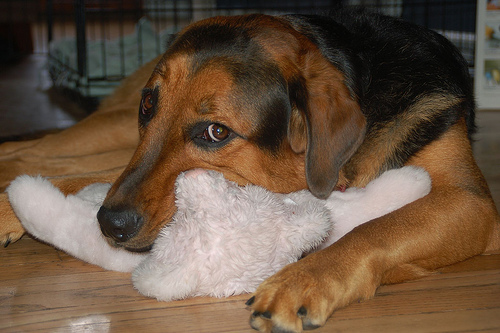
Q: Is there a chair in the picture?
A: No, there are no chairs.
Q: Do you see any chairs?
A: No, there are no chairs.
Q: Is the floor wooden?
A: Yes, the floor is wooden.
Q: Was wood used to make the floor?
A: Yes, the floor is made of wood.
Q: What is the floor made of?
A: The floor is made of wood.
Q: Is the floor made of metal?
A: No, the floor is made of wood.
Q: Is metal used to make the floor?
A: No, the floor is made of wood.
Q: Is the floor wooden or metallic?
A: The floor is wooden.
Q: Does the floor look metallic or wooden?
A: The floor is wooden.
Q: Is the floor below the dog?
A: Yes, the floor is below the dog.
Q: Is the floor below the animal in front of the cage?
A: Yes, the floor is below the dog.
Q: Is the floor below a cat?
A: No, the floor is below the dog.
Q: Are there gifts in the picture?
A: No, there are no gifts.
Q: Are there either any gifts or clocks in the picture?
A: No, there are no gifts or clocks.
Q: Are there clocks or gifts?
A: No, there are no gifts or clocks.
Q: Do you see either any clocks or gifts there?
A: No, there are no gifts or clocks.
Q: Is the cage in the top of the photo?
A: Yes, the cage is in the top of the image.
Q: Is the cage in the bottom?
A: No, the cage is in the top of the image.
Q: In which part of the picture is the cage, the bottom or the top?
A: The cage is in the top of the image.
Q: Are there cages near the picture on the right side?
A: Yes, there is a cage near the picture.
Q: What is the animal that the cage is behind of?
A: The animal is a dog.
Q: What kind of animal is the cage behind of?
A: The cage is behind the dog.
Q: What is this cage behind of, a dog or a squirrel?
A: The cage is behind a dog.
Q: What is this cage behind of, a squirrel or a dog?
A: The cage is behind a dog.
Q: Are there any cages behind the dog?
A: Yes, there is a cage behind the dog.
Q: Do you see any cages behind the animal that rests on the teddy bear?
A: Yes, there is a cage behind the dog.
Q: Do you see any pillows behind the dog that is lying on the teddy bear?
A: No, there is a cage behind the dog.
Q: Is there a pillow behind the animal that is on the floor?
A: No, there is a cage behind the dog.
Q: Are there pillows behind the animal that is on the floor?
A: No, there is a cage behind the dog.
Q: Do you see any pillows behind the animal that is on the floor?
A: No, there is a cage behind the dog.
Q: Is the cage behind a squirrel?
A: No, the cage is behind the dog.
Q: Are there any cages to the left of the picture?
A: Yes, there is a cage to the left of the picture.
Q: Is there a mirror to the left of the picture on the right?
A: No, there is a cage to the left of the picture.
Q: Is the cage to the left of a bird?
A: No, the cage is to the left of the picture.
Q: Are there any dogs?
A: Yes, there is a dog.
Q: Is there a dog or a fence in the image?
A: Yes, there is a dog.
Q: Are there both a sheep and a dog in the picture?
A: No, there is a dog but no sheep.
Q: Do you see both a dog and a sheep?
A: No, there is a dog but no sheep.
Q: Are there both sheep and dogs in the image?
A: No, there is a dog but no sheep.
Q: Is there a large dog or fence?
A: Yes, there is a large dog.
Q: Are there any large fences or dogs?
A: Yes, there is a large dog.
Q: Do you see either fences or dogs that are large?
A: Yes, the dog is large.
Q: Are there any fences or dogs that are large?
A: Yes, the dog is large.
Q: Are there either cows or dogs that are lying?
A: Yes, the dog is lying.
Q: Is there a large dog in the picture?
A: Yes, there is a large dog.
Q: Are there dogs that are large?
A: Yes, there is a dog that is large.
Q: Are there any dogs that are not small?
A: Yes, there is a large dog.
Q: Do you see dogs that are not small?
A: Yes, there is a large dog.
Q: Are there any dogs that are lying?
A: Yes, there is a dog that is lying.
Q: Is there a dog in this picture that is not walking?
A: Yes, there is a dog that is lying.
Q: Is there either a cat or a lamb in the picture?
A: No, there are no cats or lambs.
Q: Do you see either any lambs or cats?
A: No, there are no cats or lambs.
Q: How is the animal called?
A: The animal is a dog.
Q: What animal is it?
A: The animal is a dog.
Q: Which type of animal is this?
A: This is a dog.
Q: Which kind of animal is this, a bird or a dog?
A: This is a dog.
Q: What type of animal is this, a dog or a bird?
A: This is a dog.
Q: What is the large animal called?
A: The animal is a dog.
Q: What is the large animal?
A: The animal is a dog.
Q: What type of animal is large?
A: The animal is a dog.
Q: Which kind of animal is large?
A: The animal is a dog.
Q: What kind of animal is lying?
A: The animal is a dog.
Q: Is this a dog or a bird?
A: This is a dog.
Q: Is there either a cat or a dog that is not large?
A: No, there is a dog but it is large.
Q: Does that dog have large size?
A: Yes, the dog is large.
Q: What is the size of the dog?
A: The dog is large.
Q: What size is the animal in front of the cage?
A: The dog is large.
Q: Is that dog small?
A: No, the dog is large.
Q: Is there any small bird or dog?
A: No, there is a dog but it is large.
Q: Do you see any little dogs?
A: No, there is a dog but it is large.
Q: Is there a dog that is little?
A: No, there is a dog but it is large.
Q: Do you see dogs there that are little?
A: No, there is a dog but it is large.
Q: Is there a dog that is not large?
A: No, there is a dog but it is large.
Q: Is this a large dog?
A: Yes, this is a large dog.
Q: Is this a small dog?
A: No, this is a large dog.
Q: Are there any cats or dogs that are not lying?
A: No, there is a dog but it is lying.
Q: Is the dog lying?
A: Yes, the dog is lying.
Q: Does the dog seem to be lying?
A: Yes, the dog is lying.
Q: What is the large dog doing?
A: The dog is lying.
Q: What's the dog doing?
A: The dog is lying.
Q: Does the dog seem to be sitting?
A: No, the dog is lying.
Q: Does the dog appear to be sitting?
A: No, the dog is lying.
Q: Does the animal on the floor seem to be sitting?
A: No, the dog is lying.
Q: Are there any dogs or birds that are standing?
A: No, there is a dog but it is lying.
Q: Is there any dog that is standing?
A: No, there is a dog but it is lying.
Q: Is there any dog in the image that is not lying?
A: No, there is a dog but it is lying.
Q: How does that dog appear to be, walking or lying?
A: The dog is lying.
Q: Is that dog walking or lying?
A: The dog is lying.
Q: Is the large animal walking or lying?
A: The dog is lying.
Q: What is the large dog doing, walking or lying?
A: The dog is lying.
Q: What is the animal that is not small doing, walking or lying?
A: The dog is lying.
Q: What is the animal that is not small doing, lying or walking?
A: The dog is lying.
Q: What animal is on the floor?
A: The dog is on the floor.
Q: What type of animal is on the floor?
A: The animal is a dog.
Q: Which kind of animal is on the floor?
A: The animal is a dog.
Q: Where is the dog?
A: The dog is on the floor.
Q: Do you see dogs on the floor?
A: Yes, there is a dog on the floor.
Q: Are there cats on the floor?
A: No, there is a dog on the floor.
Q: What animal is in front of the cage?
A: The dog is in front of the cage.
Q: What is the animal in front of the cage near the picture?
A: The animal is a dog.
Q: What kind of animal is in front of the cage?
A: The animal is a dog.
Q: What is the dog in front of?
A: The dog is in front of the cage.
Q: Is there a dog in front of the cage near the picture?
A: Yes, there is a dog in front of the cage.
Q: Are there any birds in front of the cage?
A: No, there is a dog in front of the cage.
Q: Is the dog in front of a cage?
A: Yes, the dog is in front of a cage.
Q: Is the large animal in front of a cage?
A: Yes, the dog is in front of a cage.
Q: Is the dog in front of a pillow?
A: No, the dog is in front of a cage.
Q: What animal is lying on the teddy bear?
A: The dog is lying on the teddy bear.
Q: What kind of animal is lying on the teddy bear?
A: The animal is a dog.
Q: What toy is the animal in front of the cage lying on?
A: The dog is lying on the teddy bear.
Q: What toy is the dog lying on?
A: The dog is lying on the teddy bear.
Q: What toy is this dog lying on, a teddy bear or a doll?
A: The dog is lying on a teddy bear.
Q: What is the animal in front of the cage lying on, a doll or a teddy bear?
A: The dog is lying on a teddy bear.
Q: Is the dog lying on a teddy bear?
A: Yes, the dog is lying on a teddy bear.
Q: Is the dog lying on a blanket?
A: No, the dog is lying on a teddy bear.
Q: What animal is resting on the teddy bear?
A: The dog is resting on the teddy bear.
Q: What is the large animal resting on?
A: The dog is resting on the teddy bear.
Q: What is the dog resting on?
A: The dog is resting on the teddy bear.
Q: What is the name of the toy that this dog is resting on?
A: The toy is a teddy bear.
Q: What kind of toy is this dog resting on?
A: The dog is resting on the teddy bear.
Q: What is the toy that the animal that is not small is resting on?
A: The toy is a teddy bear.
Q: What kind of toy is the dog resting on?
A: The dog is resting on the teddy bear.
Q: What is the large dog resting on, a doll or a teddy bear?
A: The dog is resting on a teddy bear.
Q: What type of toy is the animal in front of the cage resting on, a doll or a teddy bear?
A: The dog is resting on a teddy bear.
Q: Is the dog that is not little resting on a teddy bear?
A: Yes, the dog is resting on a teddy bear.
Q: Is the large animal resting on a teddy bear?
A: Yes, the dog is resting on a teddy bear.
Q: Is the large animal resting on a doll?
A: No, the dog is resting on a teddy bear.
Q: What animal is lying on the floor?
A: The dog is lying on the floor.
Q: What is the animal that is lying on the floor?
A: The animal is a dog.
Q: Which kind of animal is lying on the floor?
A: The animal is a dog.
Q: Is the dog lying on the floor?
A: Yes, the dog is lying on the floor.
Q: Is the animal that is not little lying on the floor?
A: Yes, the dog is lying on the floor.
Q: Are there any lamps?
A: No, there are no lamps.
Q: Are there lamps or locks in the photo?
A: No, there are no lamps or locks.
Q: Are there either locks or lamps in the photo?
A: No, there are no lamps or locks.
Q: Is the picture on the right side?
A: Yes, the picture is on the right of the image.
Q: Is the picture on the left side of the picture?
A: No, the picture is on the right of the image.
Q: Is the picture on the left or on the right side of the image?
A: The picture is on the right of the image.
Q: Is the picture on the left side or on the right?
A: The picture is on the right of the image.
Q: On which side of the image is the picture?
A: The picture is on the right of the image.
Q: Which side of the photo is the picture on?
A: The picture is on the right of the image.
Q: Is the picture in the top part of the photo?
A: Yes, the picture is in the top of the image.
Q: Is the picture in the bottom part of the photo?
A: No, the picture is in the top of the image.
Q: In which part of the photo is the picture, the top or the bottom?
A: The picture is in the top of the image.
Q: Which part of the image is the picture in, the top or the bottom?
A: The picture is in the top of the image.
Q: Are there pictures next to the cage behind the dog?
A: Yes, there is a picture next to the cage.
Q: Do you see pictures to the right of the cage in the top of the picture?
A: Yes, there is a picture to the right of the cage.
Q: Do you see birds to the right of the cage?
A: No, there is a picture to the right of the cage.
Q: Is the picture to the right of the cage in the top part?
A: Yes, the picture is to the right of the cage.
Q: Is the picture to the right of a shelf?
A: No, the picture is to the right of the cage.